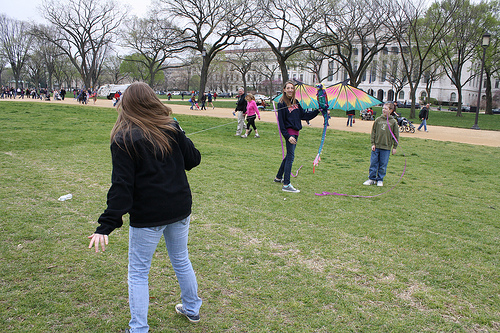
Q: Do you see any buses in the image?
A: No, there are no buses.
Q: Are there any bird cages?
A: No, there are no bird cages.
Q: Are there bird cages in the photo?
A: No, there are no bird cages.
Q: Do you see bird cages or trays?
A: No, there are no bird cages or trays.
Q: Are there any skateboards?
A: No, there are no skateboards.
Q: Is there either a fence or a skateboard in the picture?
A: No, there are no skateboards or fences.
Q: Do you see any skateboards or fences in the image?
A: No, there are no skateboards or fences.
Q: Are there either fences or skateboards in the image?
A: No, there are no skateboards or fences.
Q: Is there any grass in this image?
A: Yes, there is grass.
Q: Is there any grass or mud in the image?
A: Yes, there is grass.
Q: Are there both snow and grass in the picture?
A: No, there is grass but no snow.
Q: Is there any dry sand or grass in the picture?
A: Yes, there is dry grass.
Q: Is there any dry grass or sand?
A: Yes, there is dry grass.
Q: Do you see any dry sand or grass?
A: Yes, there is dry grass.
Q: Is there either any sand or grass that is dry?
A: Yes, the grass is dry.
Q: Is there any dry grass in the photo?
A: Yes, there is dry grass.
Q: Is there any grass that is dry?
A: Yes, there is grass that is dry.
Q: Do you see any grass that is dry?
A: Yes, there is grass that is dry.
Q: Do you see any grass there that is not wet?
A: Yes, there is dry grass.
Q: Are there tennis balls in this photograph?
A: No, there are no tennis balls.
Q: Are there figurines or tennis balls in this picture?
A: No, there are no tennis balls or figurines.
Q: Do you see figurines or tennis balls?
A: No, there are no tennis balls or figurines.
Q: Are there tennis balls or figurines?
A: No, there are no tennis balls or figurines.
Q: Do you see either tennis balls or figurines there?
A: No, there are no tennis balls or figurines.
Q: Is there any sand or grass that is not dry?
A: No, there is grass but it is dry.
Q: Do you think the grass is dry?
A: Yes, the grass is dry.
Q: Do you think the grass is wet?
A: No, the grass is dry.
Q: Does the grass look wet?
A: No, the grass is dry.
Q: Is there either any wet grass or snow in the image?
A: No, there is grass but it is dry.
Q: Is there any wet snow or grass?
A: No, there is grass but it is dry.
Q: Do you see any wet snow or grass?
A: No, there is grass but it is dry.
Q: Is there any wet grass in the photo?
A: No, there is grass but it is dry.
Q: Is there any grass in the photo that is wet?
A: No, there is grass but it is dry.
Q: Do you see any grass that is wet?
A: No, there is grass but it is dry.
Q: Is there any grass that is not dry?
A: No, there is grass but it is dry.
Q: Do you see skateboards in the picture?
A: No, there are no skateboards.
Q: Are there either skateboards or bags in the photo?
A: No, there are no skateboards or bags.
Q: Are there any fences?
A: No, there are no fences.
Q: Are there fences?
A: No, there are no fences.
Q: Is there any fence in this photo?
A: No, there are no fences.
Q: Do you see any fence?
A: No, there are no fences.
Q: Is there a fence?
A: No, there are no fences.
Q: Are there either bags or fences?
A: No, there are no fences or bags.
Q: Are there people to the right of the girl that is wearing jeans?
A: Yes, there are people to the right of the girl.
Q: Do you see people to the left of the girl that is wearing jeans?
A: No, the people are to the right of the girl.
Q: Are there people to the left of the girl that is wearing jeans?
A: No, the people are to the right of the girl.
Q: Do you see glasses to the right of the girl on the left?
A: No, there are people to the right of the girl.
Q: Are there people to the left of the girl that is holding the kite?
A: Yes, there are people to the left of the girl.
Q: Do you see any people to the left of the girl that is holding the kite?
A: Yes, there are people to the left of the girl.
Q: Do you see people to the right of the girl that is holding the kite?
A: No, the people are to the left of the girl.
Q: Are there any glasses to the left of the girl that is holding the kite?
A: No, there are people to the left of the girl.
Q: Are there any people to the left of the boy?
A: Yes, there are people to the left of the boy.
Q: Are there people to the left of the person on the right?
A: Yes, there are people to the left of the boy.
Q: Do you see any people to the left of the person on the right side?
A: Yes, there are people to the left of the boy.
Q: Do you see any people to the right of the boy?
A: No, the people are to the left of the boy.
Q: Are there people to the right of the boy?
A: No, the people are to the left of the boy.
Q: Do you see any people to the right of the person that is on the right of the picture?
A: No, the people are to the left of the boy.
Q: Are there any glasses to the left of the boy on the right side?
A: No, there are people to the left of the boy.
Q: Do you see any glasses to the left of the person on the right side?
A: No, there are people to the left of the boy.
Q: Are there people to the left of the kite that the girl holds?
A: Yes, there are people to the left of the kite.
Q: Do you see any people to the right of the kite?
A: No, the people are to the left of the kite.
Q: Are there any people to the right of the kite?
A: No, the people are to the left of the kite.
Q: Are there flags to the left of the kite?
A: No, there are people to the left of the kite.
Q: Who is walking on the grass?
A: The people are walking on the grass.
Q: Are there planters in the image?
A: No, there are no planters.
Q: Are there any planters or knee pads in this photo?
A: No, there are no planters or knee pads.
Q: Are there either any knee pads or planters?
A: No, there are no planters or knee pads.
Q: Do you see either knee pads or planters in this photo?
A: No, there are no planters or knee pads.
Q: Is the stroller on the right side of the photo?
A: Yes, the stroller is on the right of the image.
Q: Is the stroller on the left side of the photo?
A: No, the stroller is on the right of the image.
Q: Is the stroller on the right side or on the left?
A: The stroller is on the right of the image.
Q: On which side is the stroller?
A: The stroller is on the right of the image.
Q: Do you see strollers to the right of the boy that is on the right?
A: Yes, there is a stroller to the right of the boy.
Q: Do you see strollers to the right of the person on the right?
A: Yes, there is a stroller to the right of the boy.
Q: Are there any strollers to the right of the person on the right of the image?
A: Yes, there is a stroller to the right of the boy.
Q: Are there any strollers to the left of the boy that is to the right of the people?
A: No, the stroller is to the right of the boy.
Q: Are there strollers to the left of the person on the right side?
A: No, the stroller is to the right of the boy.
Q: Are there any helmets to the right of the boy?
A: No, there is a stroller to the right of the boy.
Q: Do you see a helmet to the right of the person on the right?
A: No, there is a stroller to the right of the boy.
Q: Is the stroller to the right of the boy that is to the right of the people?
A: Yes, the stroller is to the right of the boy.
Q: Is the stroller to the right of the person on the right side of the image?
A: Yes, the stroller is to the right of the boy.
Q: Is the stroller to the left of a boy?
A: No, the stroller is to the right of a boy.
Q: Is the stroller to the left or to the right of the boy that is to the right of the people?
A: The stroller is to the right of the boy.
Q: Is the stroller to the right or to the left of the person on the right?
A: The stroller is to the right of the boy.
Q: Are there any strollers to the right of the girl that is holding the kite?
A: Yes, there is a stroller to the right of the girl.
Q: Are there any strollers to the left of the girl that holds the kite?
A: No, the stroller is to the right of the girl.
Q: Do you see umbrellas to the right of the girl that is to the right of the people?
A: No, there is a stroller to the right of the girl.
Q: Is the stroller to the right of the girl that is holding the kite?
A: Yes, the stroller is to the right of the girl.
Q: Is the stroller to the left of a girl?
A: No, the stroller is to the right of a girl.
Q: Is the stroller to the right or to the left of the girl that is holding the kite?
A: The stroller is to the right of the girl.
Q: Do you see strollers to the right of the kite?
A: Yes, there is a stroller to the right of the kite.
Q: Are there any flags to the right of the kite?
A: No, there is a stroller to the right of the kite.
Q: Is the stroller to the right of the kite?
A: Yes, the stroller is to the right of the kite.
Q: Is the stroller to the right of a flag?
A: No, the stroller is to the right of the kite.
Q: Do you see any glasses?
A: No, there are no glasses.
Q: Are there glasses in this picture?
A: No, there are no glasses.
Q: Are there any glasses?
A: No, there are no glasses.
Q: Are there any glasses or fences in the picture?
A: No, there are no glasses or fences.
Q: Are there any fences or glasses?
A: No, there are no glasses or fences.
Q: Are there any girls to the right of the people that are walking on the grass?
A: Yes, there is a girl to the right of the people.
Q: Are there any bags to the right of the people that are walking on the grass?
A: No, there is a girl to the right of the people.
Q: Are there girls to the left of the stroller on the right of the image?
A: Yes, there is a girl to the left of the stroller.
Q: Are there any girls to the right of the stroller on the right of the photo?
A: No, the girl is to the left of the stroller.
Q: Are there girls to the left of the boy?
A: Yes, there is a girl to the left of the boy.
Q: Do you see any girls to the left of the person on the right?
A: Yes, there is a girl to the left of the boy.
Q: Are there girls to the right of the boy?
A: No, the girl is to the left of the boy.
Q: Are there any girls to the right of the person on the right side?
A: No, the girl is to the left of the boy.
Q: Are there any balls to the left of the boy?
A: No, there is a girl to the left of the boy.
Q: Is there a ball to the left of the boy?
A: No, there is a girl to the left of the boy.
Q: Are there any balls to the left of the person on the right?
A: No, there is a girl to the left of the boy.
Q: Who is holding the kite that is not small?
A: The girl is holding the kite.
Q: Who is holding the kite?
A: The girl is holding the kite.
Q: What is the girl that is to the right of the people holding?
A: The girl is holding the kite.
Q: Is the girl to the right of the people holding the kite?
A: Yes, the girl is holding the kite.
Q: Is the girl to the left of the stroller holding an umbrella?
A: No, the girl is holding the kite.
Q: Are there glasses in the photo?
A: No, there are no glasses.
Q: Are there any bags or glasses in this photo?
A: No, there are no glasses or bags.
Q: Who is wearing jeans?
A: The girl is wearing jeans.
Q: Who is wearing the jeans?
A: The girl is wearing jeans.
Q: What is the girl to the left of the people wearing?
A: The girl is wearing jeans.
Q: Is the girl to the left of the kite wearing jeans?
A: Yes, the girl is wearing jeans.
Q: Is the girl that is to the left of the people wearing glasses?
A: No, the girl is wearing jeans.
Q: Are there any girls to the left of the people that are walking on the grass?
A: Yes, there is a girl to the left of the people.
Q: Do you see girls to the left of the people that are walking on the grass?
A: Yes, there is a girl to the left of the people.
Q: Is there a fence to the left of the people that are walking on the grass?
A: No, there is a girl to the left of the people.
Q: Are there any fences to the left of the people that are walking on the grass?
A: No, there is a girl to the left of the people.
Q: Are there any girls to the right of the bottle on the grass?
A: Yes, there is a girl to the right of the bottle.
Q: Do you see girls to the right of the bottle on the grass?
A: Yes, there is a girl to the right of the bottle.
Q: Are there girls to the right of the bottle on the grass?
A: Yes, there is a girl to the right of the bottle.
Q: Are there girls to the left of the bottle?
A: No, the girl is to the right of the bottle.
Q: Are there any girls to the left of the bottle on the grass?
A: No, the girl is to the right of the bottle.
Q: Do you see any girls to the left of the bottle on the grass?
A: No, the girl is to the right of the bottle.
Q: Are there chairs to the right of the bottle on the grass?
A: No, there is a girl to the right of the bottle.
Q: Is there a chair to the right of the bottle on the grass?
A: No, there is a girl to the right of the bottle.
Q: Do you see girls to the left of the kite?
A: Yes, there is a girl to the left of the kite.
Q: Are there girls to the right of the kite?
A: No, the girl is to the left of the kite.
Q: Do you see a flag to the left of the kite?
A: No, there is a girl to the left of the kite.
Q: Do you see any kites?
A: Yes, there is a kite.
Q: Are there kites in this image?
A: Yes, there is a kite.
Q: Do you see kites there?
A: Yes, there is a kite.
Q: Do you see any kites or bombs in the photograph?
A: Yes, there is a kite.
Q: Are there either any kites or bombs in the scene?
A: Yes, there is a kite.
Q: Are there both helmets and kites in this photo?
A: No, there is a kite but no helmets.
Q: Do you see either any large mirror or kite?
A: Yes, there is a large kite.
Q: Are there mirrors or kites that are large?
A: Yes, the kite is large.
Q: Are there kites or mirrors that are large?
A: Yes, the kite is large.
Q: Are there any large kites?
A: Yes, there is a large kite.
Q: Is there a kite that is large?
A: Yes, there is a kite that is large.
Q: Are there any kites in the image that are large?
A: Yes, there is a kite that is large.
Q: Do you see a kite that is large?
A: Yes, there is a kite that is large.